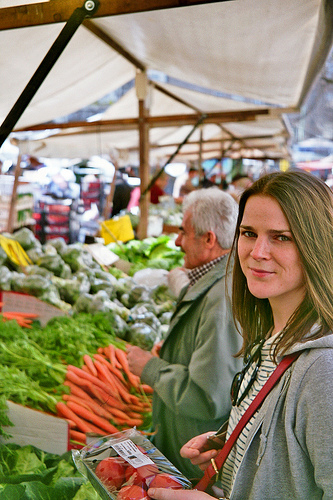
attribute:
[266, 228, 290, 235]
eye brow — black, brushy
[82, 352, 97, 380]
carrot — orange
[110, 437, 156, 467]
label — white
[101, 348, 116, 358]
carrot — large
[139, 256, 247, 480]
jacket — grey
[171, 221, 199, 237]
eyebrows — black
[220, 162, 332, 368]
hair — brown, shoulder length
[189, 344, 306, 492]
strap — red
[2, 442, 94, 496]
leaves — green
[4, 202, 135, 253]
signs — yellow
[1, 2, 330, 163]
umbrellas — large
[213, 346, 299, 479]
shirt — stripped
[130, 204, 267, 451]
man — middle aged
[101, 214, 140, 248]
paper — yellow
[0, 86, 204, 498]
market — outdoor, farmers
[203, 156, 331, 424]
woman — young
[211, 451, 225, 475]
buckle — gold